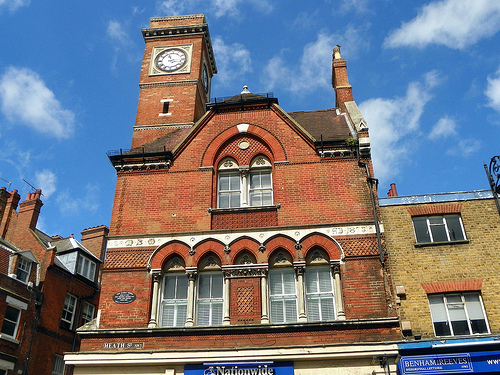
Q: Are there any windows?
A: Yes, there is a window.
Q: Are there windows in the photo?
A: Yes, there is a window.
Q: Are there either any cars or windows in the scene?
A: Yes, there is a window.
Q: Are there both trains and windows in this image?
A: No, there is a window but no trains.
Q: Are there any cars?
A: No, there are no cars.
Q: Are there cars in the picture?
A: No, there are no cars.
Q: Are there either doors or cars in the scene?
A: No, there are no cars or doors.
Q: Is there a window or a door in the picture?
A: Yes, there is a window.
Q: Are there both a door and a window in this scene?
A: No, there is a window but no doors.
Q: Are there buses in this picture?
A: No, there are no buses.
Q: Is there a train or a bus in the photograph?
A: No, there are no buses or trains.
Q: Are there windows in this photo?
A: Yes, there is a window.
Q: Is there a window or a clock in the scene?
A: Yes, there is a window.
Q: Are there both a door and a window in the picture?
A: No, there is a window but no doors.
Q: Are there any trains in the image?
A: No, there are no trains.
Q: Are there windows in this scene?
A: Yes, there is a window.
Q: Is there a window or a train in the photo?
A: Yes, there is a window.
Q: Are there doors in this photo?
A: No, there are no doors.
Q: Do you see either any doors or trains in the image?
A: No, there are no doors or trains.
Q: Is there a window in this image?
A: Yes, there is a window.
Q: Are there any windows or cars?
A: Yes, there is a window.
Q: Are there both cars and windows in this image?
A: No, there is a window but no cars.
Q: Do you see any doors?
A: No, there are no doors.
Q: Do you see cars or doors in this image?
A: No, there are no doors or cars.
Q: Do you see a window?
A: Yes, there is a window.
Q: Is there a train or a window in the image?
A: Yes, there is a window.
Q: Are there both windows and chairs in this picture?
A: No, there is a window but no chairs.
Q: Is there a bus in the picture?
A: No, there are no buses.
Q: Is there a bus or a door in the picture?
A: No, there are no buses or doors.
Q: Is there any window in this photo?
A: Yes, there is a window.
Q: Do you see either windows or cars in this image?
A: Yes, there is a window.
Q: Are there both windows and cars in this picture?
A: No, there is a window but no cars.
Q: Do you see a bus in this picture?
A: No, there are no buses.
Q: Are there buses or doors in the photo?
A: No, there are no buses or doors.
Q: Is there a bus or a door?
A: No, there are no buses or doors.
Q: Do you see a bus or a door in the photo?
A: No, there are no buses or doors.